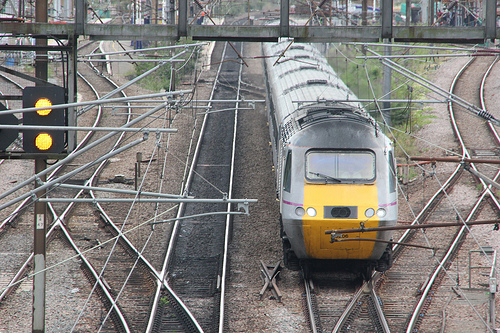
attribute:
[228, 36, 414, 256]
train — yellow, silver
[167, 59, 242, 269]
tracks — straight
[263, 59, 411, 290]
train — large, long, yellow, silver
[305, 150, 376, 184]
window — large, wide, clear, glass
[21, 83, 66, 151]
light — large, black, yellow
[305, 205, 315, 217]
light — small, round, white